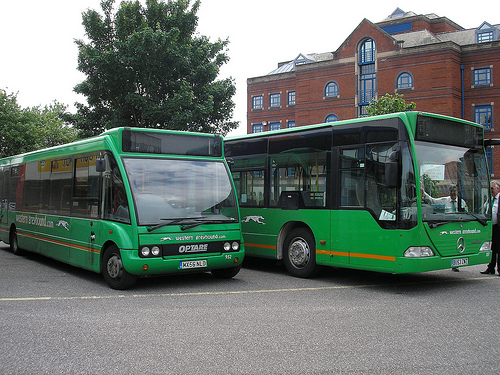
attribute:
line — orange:
[3, 221, 101, 260]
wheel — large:
[266, 213, 320, 280]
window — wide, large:
[399, 132, 490, 223]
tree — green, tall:
[56, 0, 246, 138]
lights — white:
[137, 235, 242, 260]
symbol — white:
[11, 211, 73, 232]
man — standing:
[482, 173, 499, 277]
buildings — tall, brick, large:
[234, 12, 495, 126]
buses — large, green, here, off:
[5, 103, 497, 295]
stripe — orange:
[238, 237, 405, 268]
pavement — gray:
[4, 285, 497, 371]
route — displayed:
[412, 110, 488, 152]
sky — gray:
[3, 2, 343, 79]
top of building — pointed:
[283, 7, 432, 69]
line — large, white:
[1, 274, 497, 301]